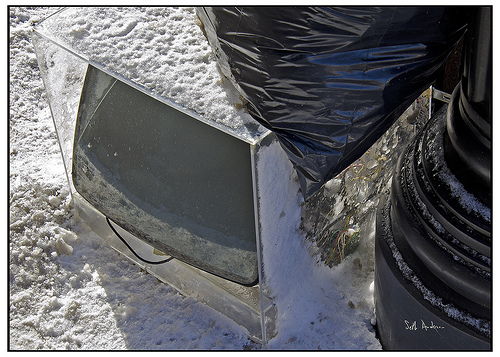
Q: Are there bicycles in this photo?
A: No, there are no bicycles.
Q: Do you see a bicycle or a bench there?
A: No, there are no bicycles or benches.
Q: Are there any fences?
A: No, there are no fences.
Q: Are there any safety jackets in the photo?
A: No, there are no safety jackets.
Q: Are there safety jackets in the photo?
A: No, there are no safety jackets.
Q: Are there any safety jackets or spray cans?
A: No, there are no safety jackets or spray cans.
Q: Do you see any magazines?
A: No, there are no magazines.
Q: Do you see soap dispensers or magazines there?
A: No, there are no magazines or soap dispensers.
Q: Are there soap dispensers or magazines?
A: No, there are no magazines or soap dispensers.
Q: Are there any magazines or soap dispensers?
A: No, there are no magazines or soap dispensers.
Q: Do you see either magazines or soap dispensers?
A: No, there are no magazines or soap dispensers.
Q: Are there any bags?
A: Yes, there is a bag.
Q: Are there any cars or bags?
A: Yes, there is a bag.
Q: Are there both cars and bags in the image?
A: No, there is a bag but no cars.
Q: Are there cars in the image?
A: No, there are no cars.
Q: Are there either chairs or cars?
A: No, there are no cars or chairs.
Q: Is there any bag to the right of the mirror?
A: Yes, there is a bag to the right of the mirror.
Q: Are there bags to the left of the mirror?
A: No, the bag is to the right of the mirror.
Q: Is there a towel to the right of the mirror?
A: No, there is a bag to the right of the mirror.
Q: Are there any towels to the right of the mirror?
A: No, there is a bag to the right of the mirror.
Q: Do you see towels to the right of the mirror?
A: No, there is a bag to the right of the mirror.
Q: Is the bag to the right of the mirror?
A: Yes, the bag is to the right of the mirror.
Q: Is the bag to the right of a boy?
A: No, the bag is to the right of the mirror.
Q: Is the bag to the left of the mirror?
A: No, the bag is to the right of the mirror.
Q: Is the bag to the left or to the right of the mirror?
A: The bag is to the right of the mirror.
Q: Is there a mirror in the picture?
A: Yes, there is a mirror.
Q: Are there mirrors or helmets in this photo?
A: Yes, there is a mirror.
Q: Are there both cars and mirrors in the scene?
A: No, there is a mirror but no cars.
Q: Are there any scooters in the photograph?
A: No, there are no scooters.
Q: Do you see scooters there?
A: No, there are no scooters.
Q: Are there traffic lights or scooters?
A: No, there are no scooters or traffic lights.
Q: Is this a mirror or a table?
A: This is a mirror.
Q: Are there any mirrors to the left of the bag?
A: Yes, there is a mirror to the left of the bag.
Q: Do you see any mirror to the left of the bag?
A: Yes, there is a mirror to the left of the bag.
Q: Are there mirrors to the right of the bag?
A: No, the mirror is to the left of the bag.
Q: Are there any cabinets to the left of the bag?
A: No, there is a mirror to the left of the bag.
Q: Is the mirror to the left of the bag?
A: Yes, the mirror is to the left of the bag.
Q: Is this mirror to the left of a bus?
A: No, the mirror is to the left of the bag.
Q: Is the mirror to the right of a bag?
A: No, the mirror is to the left of a bag.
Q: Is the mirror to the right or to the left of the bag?
A: The mirror is to the left of the bag.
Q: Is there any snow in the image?
A: Yes, there is snow.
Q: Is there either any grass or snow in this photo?
A: Yes, there is snow.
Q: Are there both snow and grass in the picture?
A: No, there is snow but no grass.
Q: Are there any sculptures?
A: No, there are no sculptures.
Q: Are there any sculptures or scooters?
A: No, there are no sculptures or scooters.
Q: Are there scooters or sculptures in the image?
A: No, there are no sculptures or scooters.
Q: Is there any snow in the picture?
A: Yes, there is snow.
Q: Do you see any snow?
A: Yes, there is snow.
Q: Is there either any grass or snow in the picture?
A: Yes, there is snow.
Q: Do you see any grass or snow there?
A: Yes, there is snow.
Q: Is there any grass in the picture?
A: No, there is no grass.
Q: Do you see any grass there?
A: No, there is no grass.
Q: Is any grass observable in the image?
A: No, there is no grass.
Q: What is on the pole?
A: The snow is on the pole.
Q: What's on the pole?
A: The snow is on the pole.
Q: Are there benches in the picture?
A: No, there are no benches.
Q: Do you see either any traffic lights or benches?
A: No, there are no benches or traffic lights.